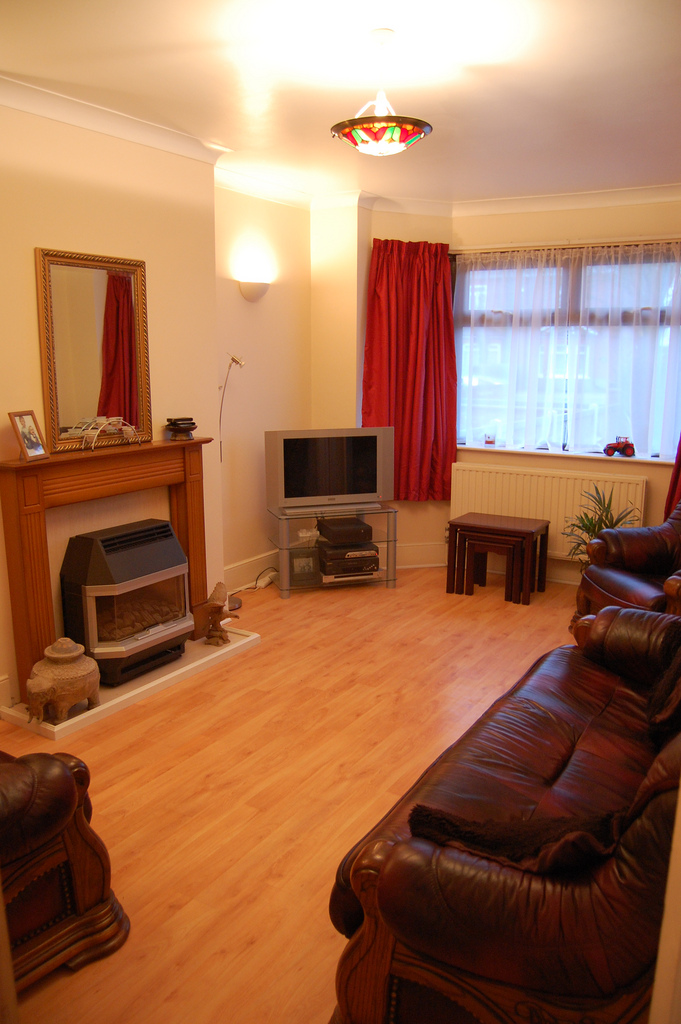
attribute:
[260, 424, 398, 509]
tv — silver